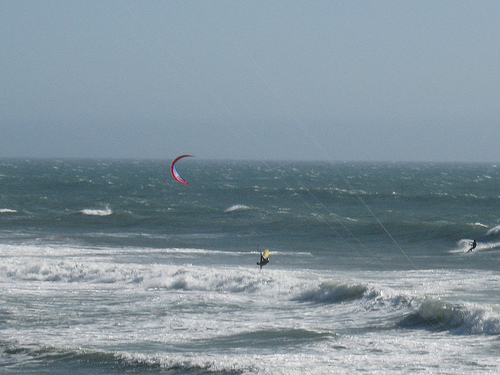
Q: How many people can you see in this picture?
A: Two.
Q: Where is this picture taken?
A: Beach.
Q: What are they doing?
A: Kite-surfing.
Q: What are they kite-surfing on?
A: Waves.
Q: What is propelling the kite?
A: Wind.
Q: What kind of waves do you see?
A: Choppy.